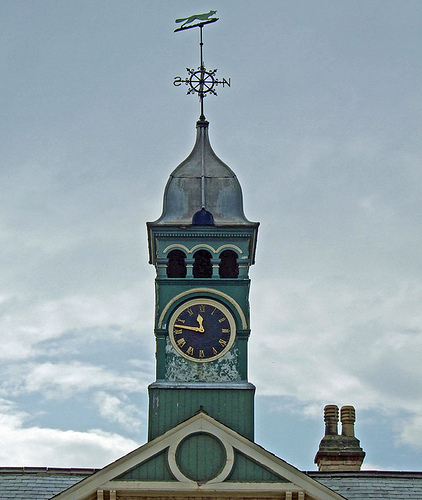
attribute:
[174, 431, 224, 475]
boards — light blue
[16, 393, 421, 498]
truss — white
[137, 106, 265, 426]
tower — blue green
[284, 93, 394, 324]
sky — cloudy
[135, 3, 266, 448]
tower — old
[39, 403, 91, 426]
sky — clear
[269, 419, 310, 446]
sky — clear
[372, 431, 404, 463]
sky — clear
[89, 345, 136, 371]
sky — clear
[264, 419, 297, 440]
sky — clear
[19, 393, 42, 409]
sky — clear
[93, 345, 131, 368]
sky — clear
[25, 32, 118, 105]
sky — clear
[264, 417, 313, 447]
sky — clear